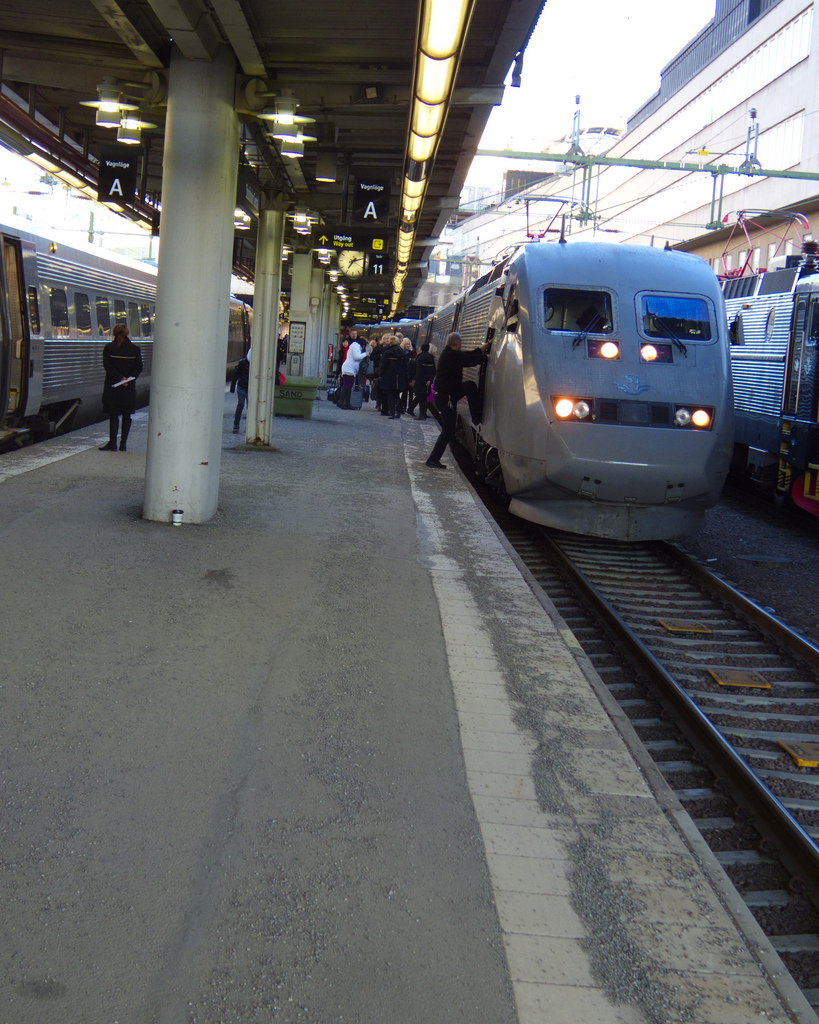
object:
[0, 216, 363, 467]
train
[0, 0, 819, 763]
picture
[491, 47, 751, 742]
out doors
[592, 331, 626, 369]
headlight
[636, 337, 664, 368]
headlight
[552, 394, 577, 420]
headlight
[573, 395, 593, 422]
headlight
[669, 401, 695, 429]
headlight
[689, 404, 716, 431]
headlight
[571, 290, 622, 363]
windshield wiper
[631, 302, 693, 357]
windshield wiper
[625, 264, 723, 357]
window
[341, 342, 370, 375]
sweater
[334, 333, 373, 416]
passenger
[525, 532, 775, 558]
tracks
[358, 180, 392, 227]
letter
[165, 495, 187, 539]
cup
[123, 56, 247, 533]
column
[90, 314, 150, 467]
person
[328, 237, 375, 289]
clock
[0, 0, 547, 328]
ceiling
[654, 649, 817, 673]
tracks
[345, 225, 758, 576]
train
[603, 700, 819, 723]
tracks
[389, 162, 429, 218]
light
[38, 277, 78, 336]
window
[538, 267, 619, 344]
window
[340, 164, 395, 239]
sign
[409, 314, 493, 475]
conductor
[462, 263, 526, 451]
door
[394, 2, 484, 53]
light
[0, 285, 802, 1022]
platform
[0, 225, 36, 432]
door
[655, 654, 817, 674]
blocks